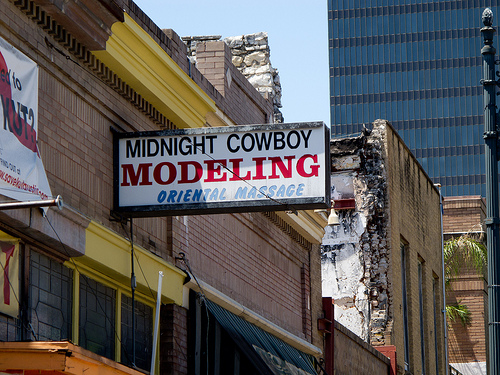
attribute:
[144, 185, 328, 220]
writing — blue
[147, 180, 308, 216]
writing — blue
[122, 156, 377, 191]
writing — red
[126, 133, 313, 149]
writing — black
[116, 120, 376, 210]
sign — white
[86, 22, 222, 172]
wall — yellow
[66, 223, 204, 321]
wall — yellow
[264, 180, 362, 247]
wall — yellow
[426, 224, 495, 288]
tree — green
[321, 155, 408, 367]
wall — broken, stone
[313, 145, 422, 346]
wall — crumbling, brick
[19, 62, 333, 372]
building — yellow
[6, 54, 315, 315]
wall — brick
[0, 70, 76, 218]
banner — hanging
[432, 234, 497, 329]
tree — palm, sticking out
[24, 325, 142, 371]
roof — small, patio, painted, orange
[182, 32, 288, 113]
brick — stone, sticking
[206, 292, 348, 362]
awning — small, black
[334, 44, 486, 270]
high rise — tall, black, blue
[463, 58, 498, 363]
pole — iron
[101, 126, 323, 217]
sign — white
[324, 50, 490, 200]
building — glass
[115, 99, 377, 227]
sign — white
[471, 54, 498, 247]
pole — metal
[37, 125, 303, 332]
building — brick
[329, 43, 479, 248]
building — office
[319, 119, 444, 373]
building — old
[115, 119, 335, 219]
sign — rectangular, white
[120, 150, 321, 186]
letters — capitalized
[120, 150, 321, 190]
word — red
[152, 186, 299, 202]
letters — blue